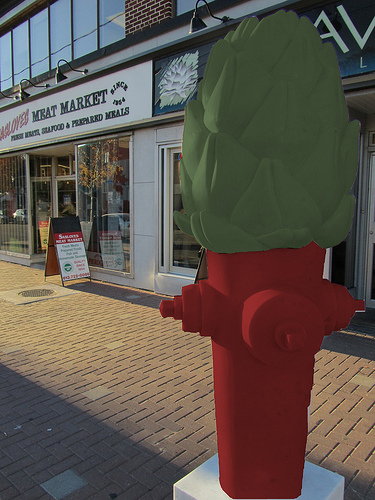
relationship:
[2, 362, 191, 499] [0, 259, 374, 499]
shade on top of sidewalk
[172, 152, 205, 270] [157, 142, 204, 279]
reflection seen in window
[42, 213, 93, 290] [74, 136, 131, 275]
sign placed by window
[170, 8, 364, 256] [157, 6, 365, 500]
artichoke on top of hydrant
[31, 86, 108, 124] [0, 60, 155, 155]
words printed on sign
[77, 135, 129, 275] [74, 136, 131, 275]
reflection seen on window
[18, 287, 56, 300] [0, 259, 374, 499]
manhole cover inside sidewalk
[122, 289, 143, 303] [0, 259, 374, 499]
part of a sidewalk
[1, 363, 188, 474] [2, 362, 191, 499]
edge of a shade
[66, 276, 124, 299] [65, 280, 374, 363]
part of a shade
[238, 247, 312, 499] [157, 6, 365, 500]
edge of a hydrant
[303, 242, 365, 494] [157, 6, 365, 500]
side of a hydrant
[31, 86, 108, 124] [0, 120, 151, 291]
words written above store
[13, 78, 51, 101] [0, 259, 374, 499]
street lamp hanging above sidewalk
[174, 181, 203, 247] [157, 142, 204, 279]
tree reflection seen in window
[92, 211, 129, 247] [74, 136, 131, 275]
car reflection seen in window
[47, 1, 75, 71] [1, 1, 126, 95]
window part of a row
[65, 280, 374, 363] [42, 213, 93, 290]
shade of sign